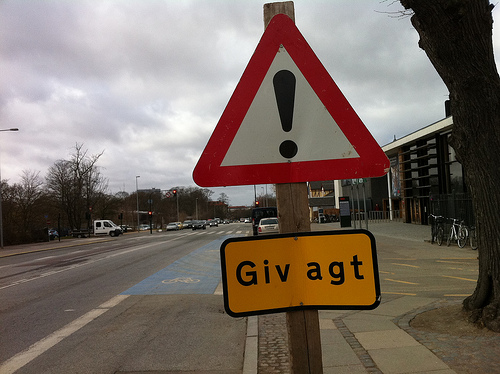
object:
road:
[4, 234, 256, 370]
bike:
[427, 211, 449, 248]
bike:
[448, 215, 470, 247]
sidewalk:
[240, 207, 499, 372]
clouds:
[53, 20, 187, 122]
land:
[3, 207, 273, 369]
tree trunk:
[396, 0, 498, 330]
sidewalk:
[298, 215, 498, 371]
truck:
[65, 218, 122, 238]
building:
[361, 120, 462, 211]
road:
[0, 202, 241, 372]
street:
[66, 236, 213, 355]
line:
[4, 291, 157, 372]